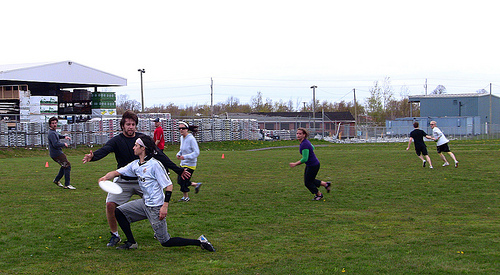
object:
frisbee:
[96, 180, 126, 196]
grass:
[244, 194, 317, 239]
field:
[0, 137, 500, 274]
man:
[426, 119, 461, 168]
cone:
[220, 152, 234, 159]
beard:
[431, 125, 439, 128]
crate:
[91, 91, 121, 102]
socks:
[153, 237, 202, 247]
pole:
[139, 74, 144, 111]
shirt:
[115, 156, 173, 207]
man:
[109, 136, 213, 253]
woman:
[170, 121, 201, 203]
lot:
[48, 114, 201, 204]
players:
[47, 114, 78, 191]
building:
[380, 90, 499, 139]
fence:
[197, 114, 376, 143]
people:
[286, 127, 332, 200]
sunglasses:
[177, 126, 190, 129]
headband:
[171, 121, 188, 129]